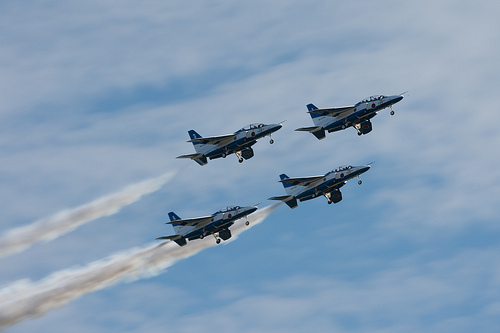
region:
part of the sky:
[311, 246, 367, 283]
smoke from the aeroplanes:
[104, 261, 154, 278]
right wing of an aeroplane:
[173, 213, 211, 223]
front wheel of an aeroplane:
[241, 218, 252, 229]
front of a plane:
[390, 87, 405, 101]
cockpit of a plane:
[361, 93, 381, 105]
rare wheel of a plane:
[320, 195, 336, 207]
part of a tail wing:
[184, 125, 196, 138]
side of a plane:
[192, 222, 209, 230]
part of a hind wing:
[290, 122, 320, 132]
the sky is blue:
[55, 18, 207, 103]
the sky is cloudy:
[42, 37, 146, 118]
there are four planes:
[162, 59, 407, 254]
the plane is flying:
[300, 63, 410, 158]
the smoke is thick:
[17, 238, 139, 309]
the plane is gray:
[295, 69, 417, 154]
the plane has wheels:
[250, 117, 290, 154]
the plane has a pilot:
[292, 89, 426, 146]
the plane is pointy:
[354, 80, 421, 124]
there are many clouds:
[20, 14, 204, 116]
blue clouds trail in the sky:
[102, 67, 240, 97]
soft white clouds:
[321, 290, 443, 312]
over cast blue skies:
[60, 71, 167, 112]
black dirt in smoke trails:
[31, 270, 148, 299]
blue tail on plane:
[155, 200, 187, 225]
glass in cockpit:
[213, 194, 243, 219]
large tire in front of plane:
[267, 130, 285, 160]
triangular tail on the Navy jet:
[264, 189, 324, 226]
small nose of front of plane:
[365, 157, 378, 174]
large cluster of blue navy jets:
[100, 41, 441, 271]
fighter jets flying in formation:
[141, 72, 437, 299]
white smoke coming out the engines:
[15, 220, 141, 294]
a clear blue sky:
[323, 227, 457, 316]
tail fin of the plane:
[181, 126, 205, 152]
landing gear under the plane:
[204, 236, 234, 248]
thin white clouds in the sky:
[281, 265, 366, 327]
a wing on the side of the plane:
[184, 135, 246, 150]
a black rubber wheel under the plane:
[356, 177, 368, 192]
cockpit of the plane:
[361, 87, 387, 102]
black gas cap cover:
[369, 101, 380, 111]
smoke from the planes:
[96, 253, 153, 285]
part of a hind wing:
[262, 188, 287, 200]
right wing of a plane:
[288, 171, 315, 179]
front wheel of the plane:
[238, 217, 255, 232]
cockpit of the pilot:
[336, 161, 348, 173]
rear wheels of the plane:
[339, 123, 364, 144]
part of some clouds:
[343, 281, 405, 319]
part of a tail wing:
[166, 207, 179, 221]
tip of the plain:
[393, 90, 405, 100]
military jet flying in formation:
[152, 111, 294, 188]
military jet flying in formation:
[291, 159, 391, 220]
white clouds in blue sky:
[60, 61, 100, 103]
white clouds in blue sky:
[261, 283, 313, 324]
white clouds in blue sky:
[335, 263, 380, 291]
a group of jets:
[143, 63, 429, 280]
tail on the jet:
[152, 203, 183, 223]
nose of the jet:
[268, 114, 286, 136]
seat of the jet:
[360, 88, 387, 105]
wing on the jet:
[168, 210, 208, 230]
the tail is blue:
[300, 100, 330, 122]